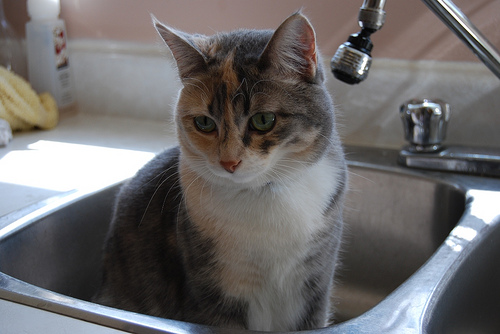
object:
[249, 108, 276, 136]
cat eye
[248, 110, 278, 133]
eye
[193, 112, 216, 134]
eye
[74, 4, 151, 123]
wall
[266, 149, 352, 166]
whiskers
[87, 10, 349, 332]
cat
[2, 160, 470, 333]
sink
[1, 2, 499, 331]
kitchen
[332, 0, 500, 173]
faucet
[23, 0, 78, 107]
bottle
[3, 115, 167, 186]
counter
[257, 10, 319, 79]
ear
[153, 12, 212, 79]
ear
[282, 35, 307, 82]
hair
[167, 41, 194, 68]
hair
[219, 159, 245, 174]
nose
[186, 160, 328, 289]
chest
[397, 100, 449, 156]
knob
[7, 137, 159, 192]
sunshine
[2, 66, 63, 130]
towel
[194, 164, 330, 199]
neck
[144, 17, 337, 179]
head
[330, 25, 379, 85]
water spout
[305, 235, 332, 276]
patch